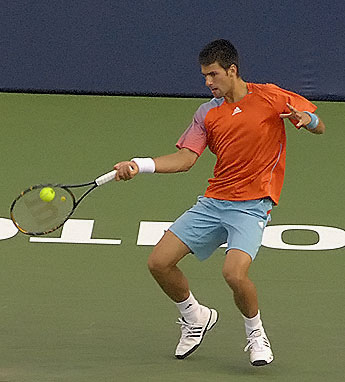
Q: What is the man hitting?
A: Ball.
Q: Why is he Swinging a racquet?
A: To hit the ball.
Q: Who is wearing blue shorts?
A: The tennis player.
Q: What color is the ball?
A: Yellow.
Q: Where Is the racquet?
A: In the player's hand.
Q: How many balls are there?
A: One.